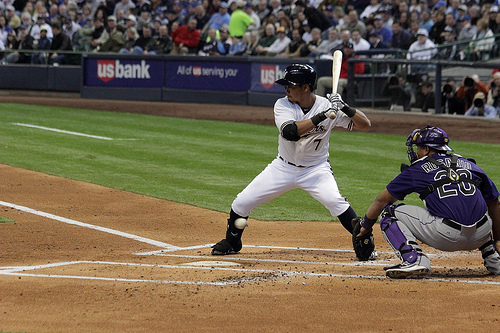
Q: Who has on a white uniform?
A: Batter.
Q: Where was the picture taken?
A: At a baseball game.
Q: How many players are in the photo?
A: Two.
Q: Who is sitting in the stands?
A: Spectators.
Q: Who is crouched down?
A: The catcher.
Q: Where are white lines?
A: On the field.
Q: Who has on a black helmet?
A: Batter.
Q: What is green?
A: Grass.